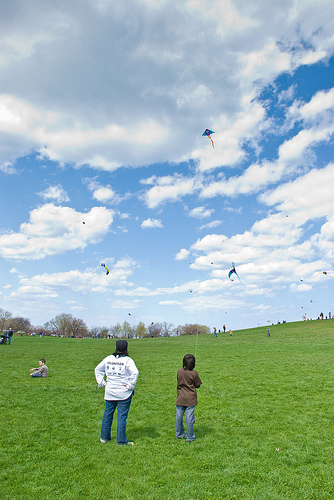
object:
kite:
[201, 125, 217, 149]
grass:
[0, 330, 334, 499]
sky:
[0, 1, 332, 338]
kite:
[99, 262, 110, 276]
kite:
[227, 262, 242, 286]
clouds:
[0, 1, 334, 181]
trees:
[178, 319, 209, 341]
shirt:
[93, 355, 140, 403]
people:
[266, 326, 272, 338]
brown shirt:
[176, 366, 202, 408]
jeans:
[102, 389, 134, 448]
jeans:
[177, 401, 199, 442]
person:
[93, 339, 140, 448]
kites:
[81, 219, 87, 228]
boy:
[30, 356, 51, 379]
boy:
[174, 353, 203, 443]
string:
[194, 273, 201, 373]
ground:
[3, 316, 332, 500]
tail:
[207, 133, 216, 147]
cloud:
[0, 202, 115, 264]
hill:
[3, 312, 333, 346]